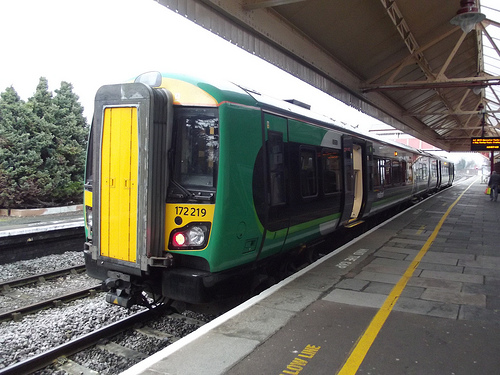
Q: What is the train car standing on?
A: Long train silver tracks.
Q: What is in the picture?
A: A train.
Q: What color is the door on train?
A: Gray and yellow.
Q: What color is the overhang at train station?
A: Brown and gray.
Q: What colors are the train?
A: Green and yellow.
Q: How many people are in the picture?
A: One.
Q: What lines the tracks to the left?
A: Trees.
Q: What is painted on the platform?
A: A yellow painted line.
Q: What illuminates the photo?
A: Sunlight and fluorescent light.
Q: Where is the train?
A: On the tracks.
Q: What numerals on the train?
A: 172219.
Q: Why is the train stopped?
A: To load passengers.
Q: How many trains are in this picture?
A: One.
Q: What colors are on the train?
A: Green and yellow.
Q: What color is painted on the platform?
A: Yellow.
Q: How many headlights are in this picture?
A: Three.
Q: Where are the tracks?
A: Under the train.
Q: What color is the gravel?
A: White.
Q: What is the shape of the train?
A: Rectangle.